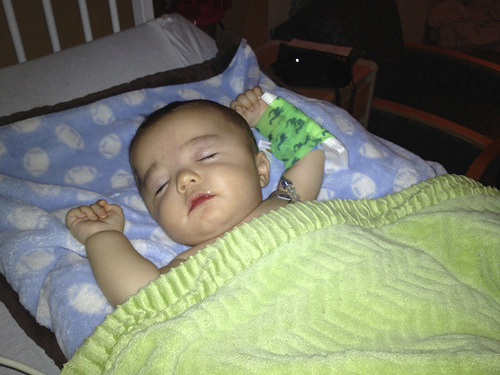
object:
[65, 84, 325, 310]
baby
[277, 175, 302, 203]
iv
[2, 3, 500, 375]
bed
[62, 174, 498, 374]
blanket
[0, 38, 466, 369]
blanket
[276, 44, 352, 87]
telephone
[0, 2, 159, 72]
headboard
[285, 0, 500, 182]
armchair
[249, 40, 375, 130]
table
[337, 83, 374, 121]
drawer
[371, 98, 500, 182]
arm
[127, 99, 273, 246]
head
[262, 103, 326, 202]
arm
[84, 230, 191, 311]
arm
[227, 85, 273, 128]
hand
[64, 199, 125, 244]
hand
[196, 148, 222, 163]
eye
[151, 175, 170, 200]
eye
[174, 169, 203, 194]
nose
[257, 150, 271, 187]
ear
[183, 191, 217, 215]
mouth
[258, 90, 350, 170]
cast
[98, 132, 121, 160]
football